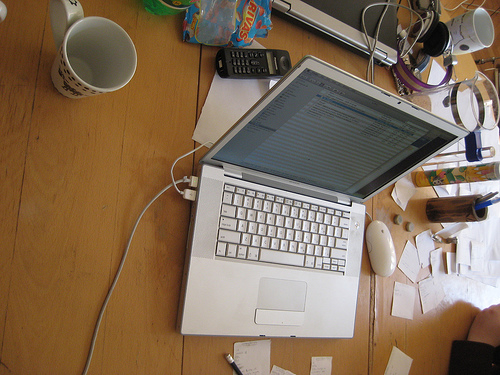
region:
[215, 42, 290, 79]
A black phone on a desk.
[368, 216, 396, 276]
A white long mouse.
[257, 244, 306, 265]
A long white spacebar.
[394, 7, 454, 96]
Purple, black and silver headphones.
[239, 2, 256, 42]
RIVAS in red lettering.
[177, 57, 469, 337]
Opened and on white laptop.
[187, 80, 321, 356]
a silver lapotp on table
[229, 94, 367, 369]
an open mac book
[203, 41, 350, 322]
a mac book that is open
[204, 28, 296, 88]
a phone on the table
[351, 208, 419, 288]
a mouse on table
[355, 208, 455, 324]
an apple mouse on table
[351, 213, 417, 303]
a white mouse on table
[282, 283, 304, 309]
the view of a white wall and chairs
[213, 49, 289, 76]
cordless phone on the table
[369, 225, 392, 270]
white mouse on the desk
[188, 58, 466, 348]
open silver laptop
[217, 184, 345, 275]
keyboard on the laptop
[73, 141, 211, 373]
cords attached to laptop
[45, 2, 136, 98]
coffee cup on the desk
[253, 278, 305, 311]
trackpad on the laptop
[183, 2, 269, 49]
plastic bag on the desk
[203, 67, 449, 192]
screen on the laptop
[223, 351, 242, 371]
pencil on the desk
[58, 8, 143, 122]
the cup is empty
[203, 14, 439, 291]
phone behind the laptop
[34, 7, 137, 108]
This is a cup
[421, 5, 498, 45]
This is a cup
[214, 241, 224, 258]
a key on a keyboard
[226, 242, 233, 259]
a key on a keyboard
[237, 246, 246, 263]
a key on a keyboard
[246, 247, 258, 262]
a key on a keyboard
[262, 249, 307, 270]
a key on a keyboard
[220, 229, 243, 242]
a key on a keyboard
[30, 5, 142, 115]
a white coffee cup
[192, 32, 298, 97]
a black phone on the desk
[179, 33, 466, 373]
an open white computer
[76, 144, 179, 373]
chord on the table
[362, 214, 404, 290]
mouse next to computer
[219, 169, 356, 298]
keyboard on the computer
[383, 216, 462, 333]
post its on the table